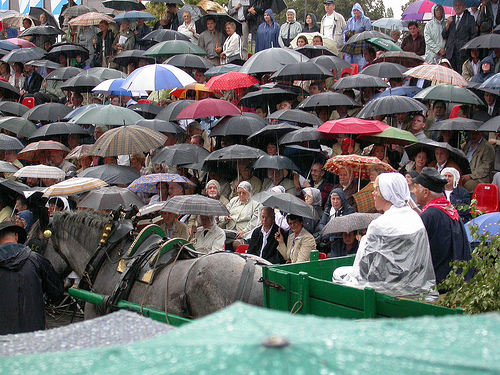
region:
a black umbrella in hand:
[253, 181, 313, 217]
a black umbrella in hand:
[172, 201, 244, 229]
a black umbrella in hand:
[160, 138, 209, 172]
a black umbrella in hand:
[208, 146, 255, 175]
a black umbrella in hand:
[216, 115, 265, 147]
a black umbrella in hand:
[267, 107, 340, 138]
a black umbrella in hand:
[306, 73, 361, 119]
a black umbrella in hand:
[250, 82, 302, 105]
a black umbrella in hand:
[349, 68, 386, 95]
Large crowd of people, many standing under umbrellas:
[2, 0, 498, 261]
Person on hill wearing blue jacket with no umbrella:
[256, 6, 281, 51]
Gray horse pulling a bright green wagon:
[26, 203, 499, 320]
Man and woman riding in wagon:
[336, 165, 481, 305]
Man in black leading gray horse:
[1, 217, 63, 336]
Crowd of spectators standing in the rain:
[2, 0, 499, 265]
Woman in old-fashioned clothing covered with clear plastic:
[345, 170, 438, 301]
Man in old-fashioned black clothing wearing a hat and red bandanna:
[407, 165, 477, 288]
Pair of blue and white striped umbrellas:
[90, 60, 198, 97]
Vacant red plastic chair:
[470, 181, 499, 214]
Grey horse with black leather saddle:
[24, 207, 269, 312]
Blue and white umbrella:
[122, 65, 194, 92]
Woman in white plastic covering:
[357, 175, 437, 289]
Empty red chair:
[471, 184, 498, 212]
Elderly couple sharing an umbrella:
[247, 191, 315, 259]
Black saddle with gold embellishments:
[84, 203, 191, 302]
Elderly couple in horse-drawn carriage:
[347, 165, 472, 291]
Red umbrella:
[177, 98, 241, 119]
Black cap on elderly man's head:
[412, 165, 448, 202]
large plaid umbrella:
[92, 122, 167, 155]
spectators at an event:
[5, 3, 494, 250]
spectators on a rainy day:
[3, 2, 494, 242]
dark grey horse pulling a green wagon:
[5, 198, 296, 330]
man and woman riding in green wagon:
[326, 155, 486, 307]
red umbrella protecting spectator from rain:
[200, 67, 263, 96]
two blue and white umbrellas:
[82, 59, 203, 98]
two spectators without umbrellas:
[197, 174, 264, 226]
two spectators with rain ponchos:
[196, 173, 266, 238]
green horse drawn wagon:
[255, 250, 472, 325]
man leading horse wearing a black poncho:
[0, 208, 71, 338]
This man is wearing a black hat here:
[421, 162, 446, 218]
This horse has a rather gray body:
[191, 250, 225, 307]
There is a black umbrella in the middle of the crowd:
[218, 137, 253, 206]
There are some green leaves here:
[470, 240, 479, 276]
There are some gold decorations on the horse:
[101, 222, 106, 254]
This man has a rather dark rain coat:
[12, 245, 28, 293]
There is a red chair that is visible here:
[473, 170, 493, 221]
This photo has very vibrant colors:
[67, 85, 282, 302]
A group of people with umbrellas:
[21, 41, 385, 328]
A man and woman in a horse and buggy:
[30, 168, 478, 312]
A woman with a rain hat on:
[219, 171, 261, 216]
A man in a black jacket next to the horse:
[6, 218, 60, 314]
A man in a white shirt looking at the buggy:
[243, 208, 280, 275]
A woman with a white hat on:
[363, 160, 413, 225]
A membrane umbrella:
[160, 93, 236, 142]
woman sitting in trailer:
[330, 151, 442, 305]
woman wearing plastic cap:
[378, 168, 412, 212]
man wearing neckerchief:
[418, 191, 459, 220]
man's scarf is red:
[417, 191, 463, 226]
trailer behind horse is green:
[249, 219, 499, 340]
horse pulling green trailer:
[20, 201, 275, 326]